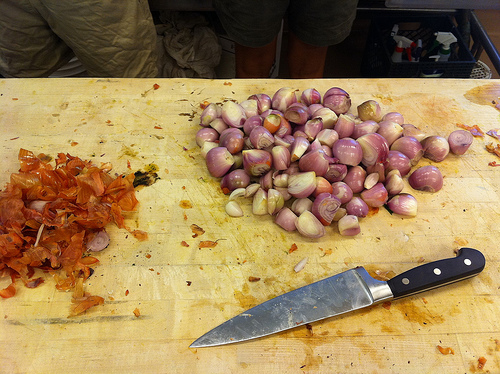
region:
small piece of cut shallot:
[405, 159, 449, 199]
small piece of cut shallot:
[387, 187, 422, 219]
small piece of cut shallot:
[337, 212, 364, 239]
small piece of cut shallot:
[203, 143, 238, 179]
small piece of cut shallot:
[242, 143, 274, 178]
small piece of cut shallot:
[220, 97, 249, 129]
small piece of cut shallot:
[282, 102, 309, 126]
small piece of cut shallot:
[268, 81, 299, 111]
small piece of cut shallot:
[317, 83, 353, 115]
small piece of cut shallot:
[379, 110, 402, 127]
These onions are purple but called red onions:
[176, 86, 456, 231]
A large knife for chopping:
[191, 234, 486, 371]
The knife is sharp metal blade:
[193, 255, 407, 372]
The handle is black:
[374, 237, 489, 306]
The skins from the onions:
[16, 137, 143, 338]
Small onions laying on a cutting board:
[124, 131, 441, 246]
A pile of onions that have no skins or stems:
[168, 82, 485, 227]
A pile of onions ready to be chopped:
[192, 79, 429, 246]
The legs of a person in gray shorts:
[221, 9, 343, 71]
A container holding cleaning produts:
[351, 7, 492, 60]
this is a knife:
[189, 246, 499, 343]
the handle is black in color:
[391, 249, 499, 284]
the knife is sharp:
[172, 273, 378, 350]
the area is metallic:
[249, 307, 304, 322]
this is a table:
[115, 283, 170, 348]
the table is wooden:
[120, 335, 162, 372]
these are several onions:
[196, 87, 468, 228]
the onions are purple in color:
[276, 106, 336, 168]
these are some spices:
[36, 182, 83, 217]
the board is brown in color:
[62, 317, 116, 349]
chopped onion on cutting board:
[410, 169, 452, 191]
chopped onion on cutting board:
[393, 200, 411, 222]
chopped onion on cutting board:
[337, 219, 359, 247]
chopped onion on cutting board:
[296, 217, 318, 246]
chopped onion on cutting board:
[283, 171, 308, 198]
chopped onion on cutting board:
[334, 141, 359, 165]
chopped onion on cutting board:
[301, 155, 323, 175]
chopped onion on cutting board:
[247, 130, 272, 143]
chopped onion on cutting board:
[211, 148, 227, 173]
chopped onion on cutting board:
[449, 130, 475, 154]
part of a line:
[160, 252, 183, 278]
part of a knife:
[261, 300, 292, 340]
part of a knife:
[268, 315, 296, 354]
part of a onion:
[275, 244, 295, 278]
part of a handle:
[421, 240, 453, 281]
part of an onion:
[321, 217, 358, 284]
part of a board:
[136, 240, 163, 287]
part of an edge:
[268, 302, 305, 355]